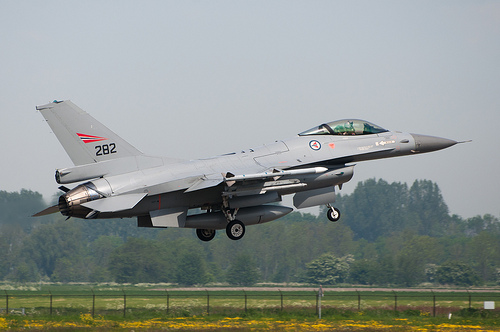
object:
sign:
[483, 300, 497, 309]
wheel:
[194, 227, 216, 241]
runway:
[145, 286, 499, 292]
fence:
[0, 290, 499, 315]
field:
[0, 315, 499, 331]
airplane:
[28, 98, 475, 242]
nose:
[407, 134, 457, 154]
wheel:
[324, 207, 342, 221]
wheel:
[225, 220, 246, 240]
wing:
[36, 98, 146, 166]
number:
[109, 142, 117, 154]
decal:
[307, 139, 322, 150]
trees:
[347, 177, 420, 242]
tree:
[225, 251, 263, 287]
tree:
[172, 247, 213, 283]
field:
[0, 287, 499, 310]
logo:
[77, 132, 107, 144]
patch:
[126, 316, 173, 328]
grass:
[0, 283, 499, 331]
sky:
[0, 0, 498, 226]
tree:
[3, 263, 40, 283]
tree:
[343, 176, 410, 244]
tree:
[406, 176, 450, 238]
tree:
[350, 257, 394, 285]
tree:
[109, 236, 159, 281]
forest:
[0, 177, 499, 285]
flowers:
[171, 323, 178, 328]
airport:
[0, 0, 499, 330]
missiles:
[180, 204, 294, 229]